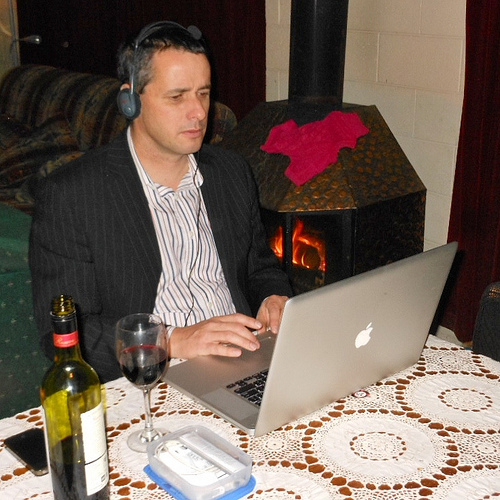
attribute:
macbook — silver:
[200, 269, 467, 419]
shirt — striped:
[132, 132, 242, 325]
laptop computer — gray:
[167, 245, 458, 430]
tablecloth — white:
[9, 359, 497, 494]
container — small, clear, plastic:
[142, 418, 259, 498]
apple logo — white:
[352, 322, 378, 350]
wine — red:
[116, 312, 174, 449]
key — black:
[234, 382, 254, 394]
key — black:
[239, 378, 248, 386]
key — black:
[224, 380, 235, 388]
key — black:
[241, 384, 259, 397]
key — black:
[253, 372, 264, 383]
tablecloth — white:
[276, 417, 494, 497]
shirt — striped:
[122, 125, 248, 363]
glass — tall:
[114, 311, 172, 456]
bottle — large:
[36, 290, 113, 499]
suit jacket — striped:
[28, 139, 280, 311]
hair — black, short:
[102, 26, 212, 98]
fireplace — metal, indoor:
[227, 79, 417, 284]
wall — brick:
[330, 17, 471, 194]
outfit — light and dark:
[27, 140, 291, 379]